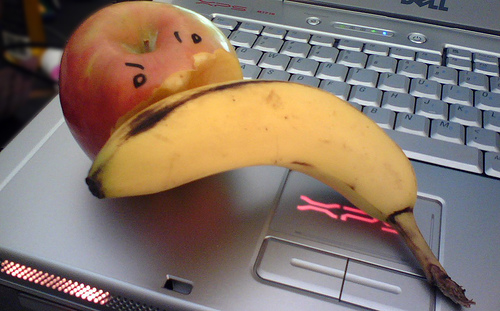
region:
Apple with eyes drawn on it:
[56, 2, 226, 109]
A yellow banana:
[68, 82, 422, 215]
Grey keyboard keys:
[261, 1, 499, 119]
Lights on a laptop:
[1, 250, 107, 307]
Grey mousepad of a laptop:
[243, 180, 360, 305]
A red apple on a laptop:
[61, 4, 257, 91]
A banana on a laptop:
[119, 78, 413, 217]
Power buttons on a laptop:
[301, 9, 441, 46]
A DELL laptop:
[365, 3, 499, 133]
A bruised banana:
[127, 79, 422, 214]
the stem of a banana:
[381, 201, 477, 309]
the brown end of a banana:
[81, 168, 113, 203]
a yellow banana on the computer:
[71, 75, 478, 310]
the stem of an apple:
[137, 32, 158, 56]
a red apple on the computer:
[55, 1, 242, 174]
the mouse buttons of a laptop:
[249, 236, 439, 309]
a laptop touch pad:
[258, 155, 443, 281]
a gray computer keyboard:
[201, 11, 498, 189]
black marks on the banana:
[116, 56, 151, 91]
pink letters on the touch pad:
[291, 191, 408, 238]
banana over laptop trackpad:
[93, 84, 425, 246]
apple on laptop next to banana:
[72, 12, 247, 138]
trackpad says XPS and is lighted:
[289, 175, 439, 255]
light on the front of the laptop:
[1, 256, 96, 309]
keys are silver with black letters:
[319, 20, 496, 178]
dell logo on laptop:
[395, 1, 457, 20]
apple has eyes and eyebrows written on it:
[119, 12, 225, 99]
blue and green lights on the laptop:
[356, 25, 405, 37]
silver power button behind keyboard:
[401, 20, 429, 57]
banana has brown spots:
[72, 80, 441, 206]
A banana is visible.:
[84, 51, 395, 229]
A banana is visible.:
[198, 144, 330, 258]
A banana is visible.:
[124, 88, 342, 213]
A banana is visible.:
[130, 5, 341, 299]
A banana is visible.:
[184, 121, 285, 236]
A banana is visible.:
[202, 88, 393, 263]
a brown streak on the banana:
[118, 78, 300, 143]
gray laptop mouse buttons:
[249, 230, 441, 309]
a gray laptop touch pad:
[263, 165, 448, 281]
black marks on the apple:
[117, 56, 152, 89]